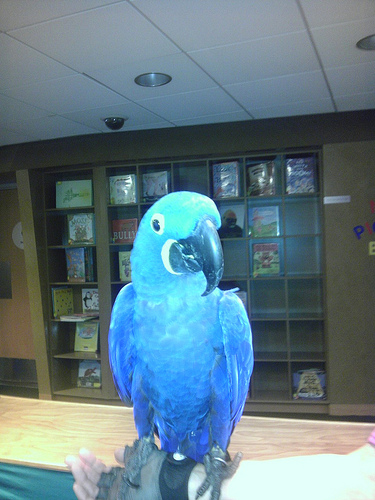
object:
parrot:
[108, 191, 254, 500]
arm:
[161, 441, 375, 498]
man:
[65, 440, 374, 498]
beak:
[187, 219, 226, 297]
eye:
[150, 216, 162, 236]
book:
[54, 179, 97, 206]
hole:
[42, 169, 92, 207]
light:
[132, 67, 173, 89]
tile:
[184, 30, 323, 89]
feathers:
[167, 322, 183, 335]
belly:
[143, 323, 211, 411]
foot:
[195, 440, 231, 499]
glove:
[99, 433, 188, 499]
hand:
[66, 436, 162, 499]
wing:
[217, 285, 255, 424]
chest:
[137, 307, 209, 355]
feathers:
[239, 339, 253, 362]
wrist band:
[159, 457, 192, 500]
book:
[108, 219, 137, 244]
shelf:
[283, 152, 320, 195]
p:
[352, 225, 362, 240]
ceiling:
[0, 0, 374, 145]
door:
[1, 179, 31, 381]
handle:
[1, 264, 13, 300]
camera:
[101, 114, 129, 130]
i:
[363, 216, 372, 236]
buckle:
[162, 453, 186, 488]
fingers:
[78, 447, 111, 472]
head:
[129, 191, 227, 296]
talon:
[197, 448, 241, 499]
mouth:
[168, 242, 201, 274]